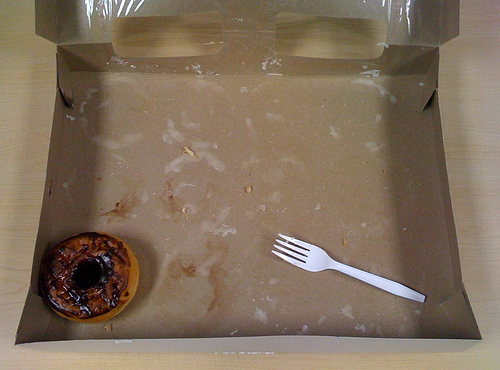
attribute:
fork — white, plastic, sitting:
[271, 233, 427, 305]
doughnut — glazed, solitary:
[39, 232, 139, 324]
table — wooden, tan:
[0, 0, 499, 369]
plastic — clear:
[35, 0, 460, 47]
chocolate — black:
[42, 232, 131, 320]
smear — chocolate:
[95, 170, 239, 327]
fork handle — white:
[333, 263, 427, 304]